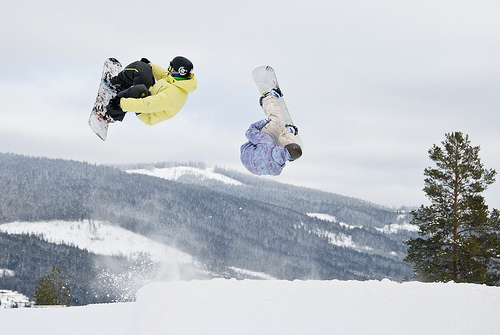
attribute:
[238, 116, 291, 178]
jacket — blue, purple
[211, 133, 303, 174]
jacket — blue, purple, man's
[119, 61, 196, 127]
jacket — yellow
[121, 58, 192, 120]
outfit — yellow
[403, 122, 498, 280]
tree — large, big, pine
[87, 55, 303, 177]
snowboarders — airborne, crouched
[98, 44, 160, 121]
pants — black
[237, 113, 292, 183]
coat — blue and purple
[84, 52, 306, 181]
men — snowboarding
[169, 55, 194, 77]
helmet — black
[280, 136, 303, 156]
helmet — dark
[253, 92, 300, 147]
pants — white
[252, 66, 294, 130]
board — snow covered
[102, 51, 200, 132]
man — upside down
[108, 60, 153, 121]
pants — black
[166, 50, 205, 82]
helmet — black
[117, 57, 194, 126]
sweatshirt — yellow